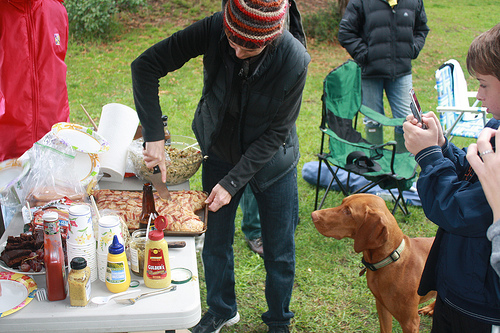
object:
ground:
[200, 120, 500, 333]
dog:
[309, 193, 435, 332]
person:
[0, 0, 69, 158]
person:
[131, 0, 311, 333]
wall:
[217, 115, 298, 186]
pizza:
[95, 189, 206, 232]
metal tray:
[96, 189, 208, 238]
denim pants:
[201, 159, 299, 327]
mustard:
[105, 235, 131, 294]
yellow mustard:
[105, 252, 131, 293]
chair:
[313, 60, 404, 217]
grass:
[69, 0, 500, 332]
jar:
[129, 229, 148, 277]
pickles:
[130, 243, 145, 277]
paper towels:
[95, 102, 141, 184]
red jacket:
[0, 0, 69, 163]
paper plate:
[0, 269, 37, 317]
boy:
[403, 29, 499, 332]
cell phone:
[408, 89, 424, 124]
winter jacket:
[336, 0, 429, 79]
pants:
[360, 70, 413, 153]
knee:
[364, 117, 383, 129]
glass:
[130, 135, 204, 186]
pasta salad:
[131, 146, 204, 186]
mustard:
[67, 256, 92, 306]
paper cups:
[66, 205, 125, 283]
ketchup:
[45, 231, 61, 300]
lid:
[42, 212, 59, 222]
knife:
[142, 142, 172, 200]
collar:
[358, 238, 405, 278]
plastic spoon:
[91, 289, 142, 304]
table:
[0, 235, 207, 331]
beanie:
[223, 0, 288, 49]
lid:
[108, 235, 124, 255]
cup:
[97, 216, 125, 284]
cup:
[65, 205, 97, 283]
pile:
[1, 121, 109, 239]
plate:
[0, 171, 199, 332]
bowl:
[129, 135, 201, 186]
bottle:
[42, 212, 68, 301]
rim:
[3, 272, 16, 278]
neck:
[354, 225, 407, 261]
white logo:
[55, 34, 61, 45]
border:
[0, 272, 38, 286]